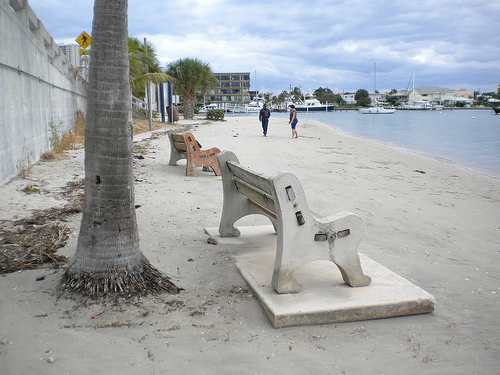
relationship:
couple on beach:
[253, 98, 305, 142] [8, 107, 498, 373]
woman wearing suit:
[286, 99, 300, 131] [286, 109, 298, 124]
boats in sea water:
[222, 94, 494, 112] [228, 109, 499, 173]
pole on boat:
[408, 63, 421, 91] [402, 80, 432, 110]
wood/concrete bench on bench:
[226, 161, 351, 241] [207, 146, 372, 290]